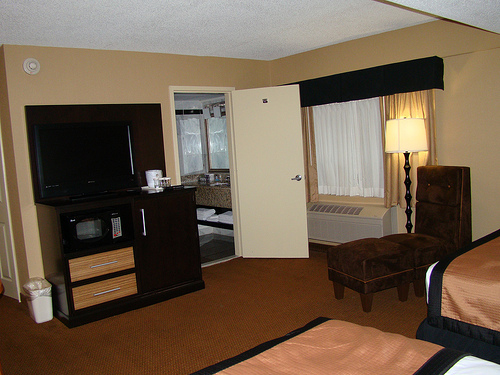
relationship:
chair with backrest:
[416, 166, 471, 255] [415, 164, 472, 240]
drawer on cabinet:
[70, 271, 138, 311] [45, 202, 199, 317]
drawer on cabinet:
[68, 243, 137, 283] [45, 202, 199, 317]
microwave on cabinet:
[63, 209, 124, 249] [45, 202, 199, 317]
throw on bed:
[275, 340, 422, 375] [448, 357, 500, 375]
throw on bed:
[434, 263, 500, 336] [425, 262, 435, 312]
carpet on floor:
[208, 267, 322, 315] [11, 329, 184, 373]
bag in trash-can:
[22, 277, 54, 302] [28, 294, 53, 325]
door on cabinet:
[135, 195, 199, 292] [45, 202, 199, 317]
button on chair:
[446, 184, 451, 191] [416, 166, 471, 255]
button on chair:
[427, 180, 431, 188] [416, 166, 471, 255]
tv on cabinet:
[32, 120, 136, 199] [45, 202, 199, 317]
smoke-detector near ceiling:
[23, 55, 42, 76] [4, 2, 379, 31]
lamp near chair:
[384, 118, 429, 236] [416, 166, 471, 255]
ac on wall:
[306, 200, 393, 236] [393, 205, 403, 236]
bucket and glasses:
[144, 170, 162, 188] [158, 177, 171, 188]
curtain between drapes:
[313, 102, 382, 197] [304, 107, 316, 199]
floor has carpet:
[11, 329, 184, 373] [208, 267, 322, 315]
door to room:
[1, 164, 8, 298] [6, 56, 500, 374]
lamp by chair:
[384, 118, 429, 236] [416, 166, 471, 255]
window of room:
[303, 101, 385, 199] [6, 56, 500, 374]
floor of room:
[11, 329, 184, 373] [6, 56, 500, 374]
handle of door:
[291, 173, 304, 184] [229, 85, 311, 260]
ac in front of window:
[306, 200, 393, 236] [303, 101, 385, 199]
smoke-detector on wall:
[23, 55, 42, 76] [48, 54, 169, 104]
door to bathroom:
[229, 85, 311, 260] [201, 95, 231, 262]